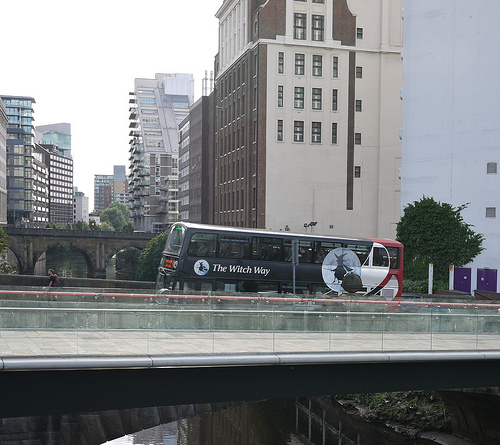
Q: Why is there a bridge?
A: Because there is a river.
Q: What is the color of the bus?
A: Blue, white and red.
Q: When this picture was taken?
A: During the day.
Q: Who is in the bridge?
A: A man.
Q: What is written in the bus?
A: The witch way.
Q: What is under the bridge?
A: A river.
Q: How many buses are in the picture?
A: One.